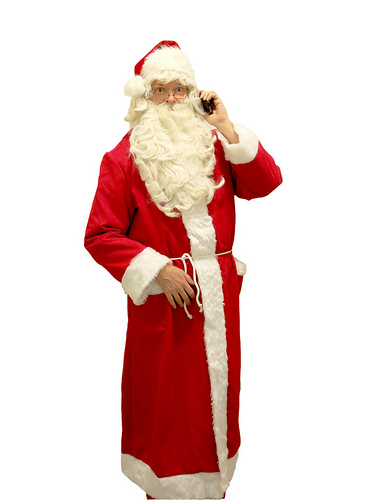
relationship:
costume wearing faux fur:
[83, 39, 282, 500] [120, 205, 240, 500]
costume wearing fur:
[83, 39, 282, 500] [178, 195, 242, 495]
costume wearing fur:
[83, 39, 282, 500] [115, 453, 241, 498]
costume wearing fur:
[83, 39, 282, 500] [182, 206, 229, 464]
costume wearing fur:
[83, 39, 282, 500] [159, 116, 197, 183]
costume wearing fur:
[83, 39, 282, 500] [187, 221, 206, 245]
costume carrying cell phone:
[83, 39, 282, 500] [182, 72, 239, 126]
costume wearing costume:
[83, 39, 282, 500] [82, 38, 283, 497]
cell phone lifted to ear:
[201, 98, 213, 115] [192, 87, 200, 97]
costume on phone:
[83, 39, 282, 500] [198, 91, 213, 117]